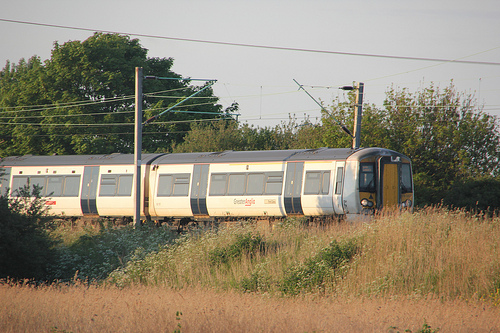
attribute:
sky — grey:
[1, 2, 499, 177]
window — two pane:
[155, 170, 193, 202]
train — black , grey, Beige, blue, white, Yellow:
[0, 146, 417, 223]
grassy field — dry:
[6, 215, 499, 331]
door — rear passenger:
[75, 163, 110, 225]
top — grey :
[2, 147, 370, 167]